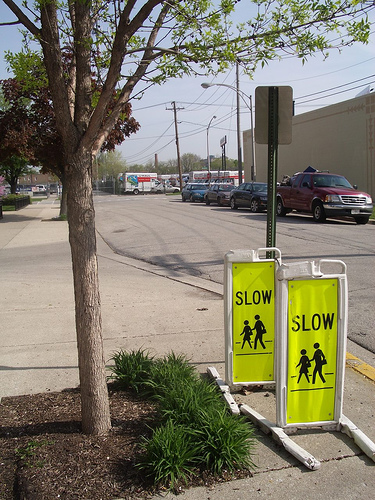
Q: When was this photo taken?
A: During daytime hours.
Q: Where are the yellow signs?
A: On the sidewalk.